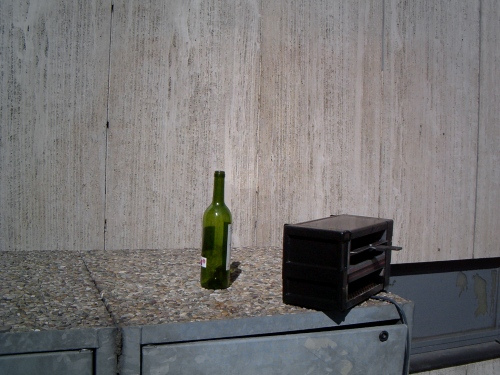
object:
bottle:
[201, 171, 232, 289]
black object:
[283, 213, 394, 321]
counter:
[0, 238, 421, 374]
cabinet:
[0, 294, 414, 374]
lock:
[373, 326, 397, 352]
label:
[215, 217, 237, 271]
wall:
[3, 1, 500, 256]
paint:
[453, 270, 492, 318]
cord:
[373, 293, 411, 374]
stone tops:
[7, 241, 413, 336]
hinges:
[77, 334, 157, 374]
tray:
[348, 238, 395, 264]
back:
[282, 223, 350, 315]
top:
[127, 299, 408, 345]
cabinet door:
[142, 324, 408, 374]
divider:
[380, 256, 493, 374]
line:
[96, 3, 118, 258]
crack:
[73, 248, 122, 331]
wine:
[201, 237, 227, 287]